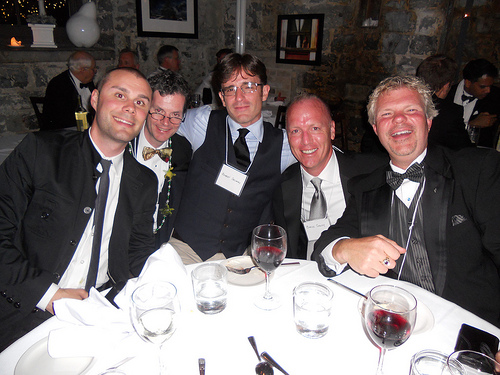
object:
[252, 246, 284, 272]
wine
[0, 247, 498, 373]
table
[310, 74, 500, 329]
man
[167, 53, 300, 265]
man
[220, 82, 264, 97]
glasses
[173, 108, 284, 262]
vest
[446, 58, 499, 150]
guy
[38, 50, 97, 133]
guy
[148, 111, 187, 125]
glasses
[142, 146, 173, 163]
gold bowtie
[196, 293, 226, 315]
liquid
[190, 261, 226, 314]
glass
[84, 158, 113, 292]
black tie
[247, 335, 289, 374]
spoon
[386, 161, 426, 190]
bowtie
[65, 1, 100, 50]
vase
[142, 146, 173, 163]
tie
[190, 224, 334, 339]
wine glass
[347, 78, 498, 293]
man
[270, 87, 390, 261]
man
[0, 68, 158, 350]
man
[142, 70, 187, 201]
man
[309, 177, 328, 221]
tie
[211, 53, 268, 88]
brown hair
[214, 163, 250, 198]
badge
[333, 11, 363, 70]
wall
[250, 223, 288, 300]
glass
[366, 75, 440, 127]
hair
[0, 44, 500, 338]
guys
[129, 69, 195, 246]
guy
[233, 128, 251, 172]
tie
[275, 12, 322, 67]
photo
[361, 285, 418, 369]
glass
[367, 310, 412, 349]
wine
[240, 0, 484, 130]
wall